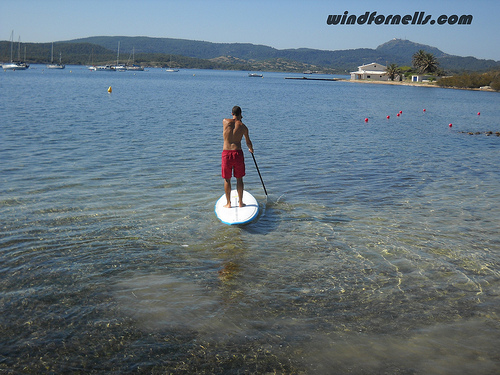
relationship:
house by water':
[350, 60, 390, 81] [301, 133, 439, 275]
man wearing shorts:
[221, 105, 254, 208] [221, 149, 246, 179]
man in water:
[221, 105, 254, 208] [0, 62, 495, 371]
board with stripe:
[195, 183, 289, 261] [217, 211, 244, 227]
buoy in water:
[365, 117, 369, 122] [0, 62, 495, 371]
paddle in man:
[248, 146, 273, 205] [221, 105, 254, 208]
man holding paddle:
[222, 105, 252, 207] [252, 152, 274, 204]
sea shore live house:
[336, 73, 498, 101] [345, 58, 394, 81]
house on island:
[350, 62, 390, 81] [338, 57, 495, 91]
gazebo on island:
[410, 73, 422, 83] [326, 55, 498, 87]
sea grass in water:
[12, 201, 495, 368] [0, 62, 495, 371]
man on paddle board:
[221, 105, 254, 208] [210, 175, 265, 232]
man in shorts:
[221, 105, 254, 208] [221, 149, 246, 179]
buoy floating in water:
[357, 112, 369, 128] [0, 62, 495, 371]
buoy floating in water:
[385, 114, 390, 123] [0, 62, 495, 371]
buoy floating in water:
[448, 122, 454, 129] [0, 62, 495, 371]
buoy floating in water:
[474, 110, 484, 120] [0, 62, 495, 371]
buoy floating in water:
[420, 107, 426, 114] [0, 62, 495, 371]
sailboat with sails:
[165, 55, 180, 73] [49, 32, 58, 63]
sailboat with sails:
[109, 39, 125, 71] [49, 32, 58, 63]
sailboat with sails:
[88, 46, 99, 71] [49, 32, 58, 63]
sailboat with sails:
[0, 28, 28, 70] [49, 32, 58, 63]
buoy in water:
[365, 117, 369, 122] [0, 62, 499, 374]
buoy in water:
[387, 115, 390, 119] [0, 62, 499, 374]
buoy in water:
[423, 109, 426, 112] [0, 62, 499, 374]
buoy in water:
[449, 123, 453, 127] [0, 62, 499, 374]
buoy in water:
[477, 112, 481, 115] [0, 62, 499, 374]